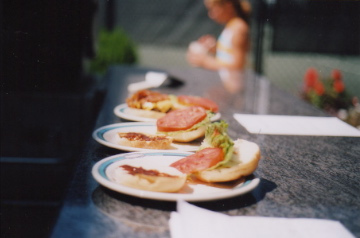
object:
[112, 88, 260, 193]
food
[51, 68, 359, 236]
counter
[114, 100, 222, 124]
plates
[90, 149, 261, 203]
first plate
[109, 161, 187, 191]
burger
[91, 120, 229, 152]
middle plate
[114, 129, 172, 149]
burger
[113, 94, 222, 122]
third plate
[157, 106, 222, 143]
burger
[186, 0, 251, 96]
kid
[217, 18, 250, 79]
shirt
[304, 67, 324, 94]
flowers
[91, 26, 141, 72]
bush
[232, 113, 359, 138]
paper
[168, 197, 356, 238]
paper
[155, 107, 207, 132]
tomato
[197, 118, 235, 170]
lettuce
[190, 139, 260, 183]
bread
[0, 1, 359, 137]
background